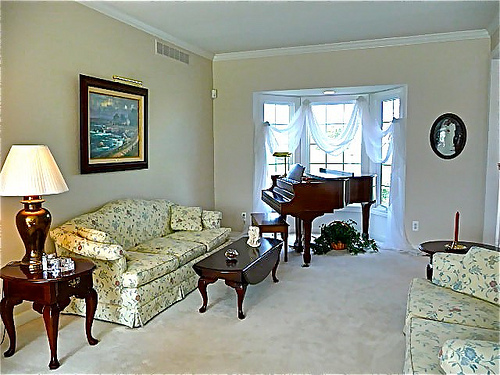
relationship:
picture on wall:
[73, 73, 153, 175] [1, 3, 215, 325]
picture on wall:
[429, 111, 468, 161] [210, 31, 490, 271]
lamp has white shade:
[1, 147, 72, 273] [0, 140, 71, 198]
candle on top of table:
[224, 246, 240, 268] [194, 232, 286, 319]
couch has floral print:
[400, 245, 500, 372] [451, 343, 493, 371]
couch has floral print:
[52, 194, 234, 325] [142, 237, 194, 261]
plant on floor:
[306, 221, 381, 255] [7, 233, 493, 374]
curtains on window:
[254, 95, 395, 172] [255, 84, 409, 242]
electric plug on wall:
[410, 219, 422, 234] [210, 31, 490, 271]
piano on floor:
[262, 168, 380, 268] [7, 233, 493, 374]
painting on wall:
[73, 73, 153, 175] [1, 3, 215, 325]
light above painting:
[114, 75, 149, 89] [73, 73, 153, 175]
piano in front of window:
[262, 168, 380, 268] [255, 84, 409, 242]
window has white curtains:
[255, 84, 409, 242] [254, 95, 395, 172]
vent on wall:
[154, 35, 195, 66] [1, 3, 215, 325]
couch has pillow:
[52, 194, 234, 325] [168, 199, 204, 235]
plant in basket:
[306, 221, 381, 255] [329, 240, 350, 252]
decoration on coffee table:
[245, 222, 262, 250] [194, 232, 286, 319]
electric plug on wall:
[411, 219, 420, 232] [210, 31, 490, 271]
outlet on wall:
[239, 209, 250, 225] [210, 31, 490, 271]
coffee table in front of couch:
[194, 232, 286, 319] [52, 194, 234, 325]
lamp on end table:
[1, 147, 72, 273] [3, 254, 100, 369]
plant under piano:
[306, 221, 381, 255] [262, 168, 380, 268]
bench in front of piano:
[246, 209, 293, 266] [262, 168, 380, 268]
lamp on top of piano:
[272, 145, 294, 179] [262, 168, 380, 268]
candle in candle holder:
[445, 208, 468, 252] [445, 236, 470, 253]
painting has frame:
[73, 73, 153, 175] [71, 65, 153, 176]